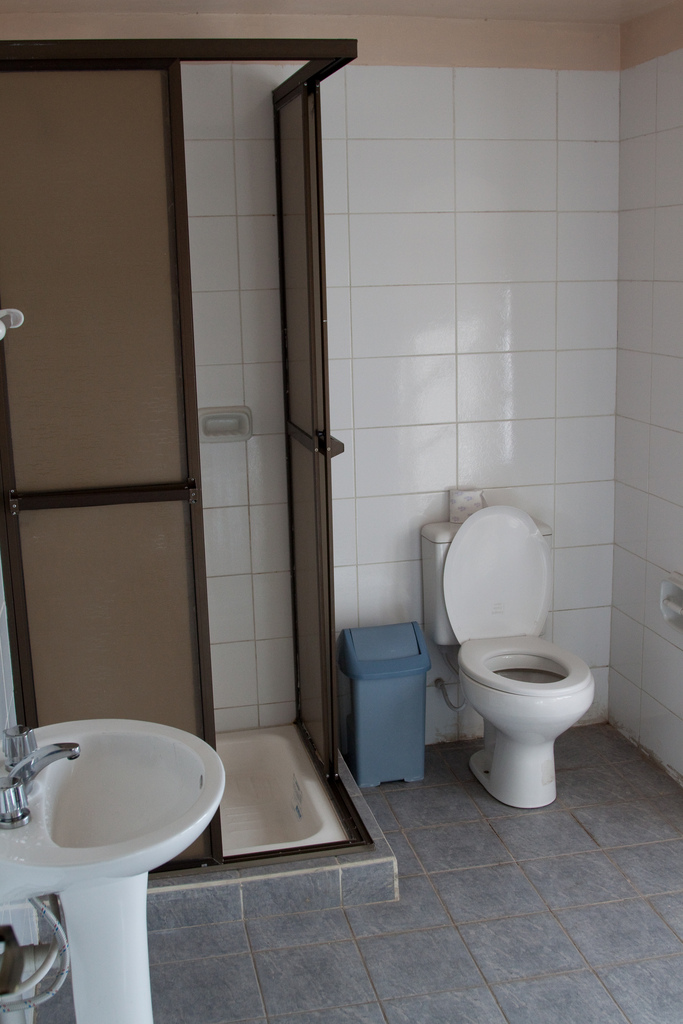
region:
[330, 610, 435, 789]
Waste bin next to toilet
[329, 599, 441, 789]
Waste bin is next to toilet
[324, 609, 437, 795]
Blue waste bin next to toilet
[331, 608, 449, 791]
Blue waste bin is next to toilet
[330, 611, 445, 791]
Trash bin next to toilet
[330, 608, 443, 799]
Trash bin is next to toilet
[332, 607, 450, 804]
Blue trash bin next to toilet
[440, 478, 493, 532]
Toilet paper on back of toilet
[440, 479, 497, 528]
Toilet paper roll is on back of toilet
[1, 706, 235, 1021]
white porcelain pedestal sink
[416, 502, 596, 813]
white porcelain toilet with open lid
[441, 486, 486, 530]
wrapped roll of toilet paper on tank of toilet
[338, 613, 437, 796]
blue plastic trash can next with swivel lid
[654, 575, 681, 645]
empty toilet paper holder on wall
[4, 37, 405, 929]
encosed shower stall with brown walls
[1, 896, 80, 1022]
water lines connecting wall to sink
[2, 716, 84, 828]
silver faucet on white pedestal sink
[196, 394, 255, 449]
small soap dish in wall of shower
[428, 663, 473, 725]
water line connecting toilet to wall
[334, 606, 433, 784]
Small blue trash can next to the shower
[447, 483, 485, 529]
Toilet paper roll on top of the toilet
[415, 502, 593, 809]
White toilet next to the blue trash can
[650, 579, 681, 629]
Toilet paper holder is empty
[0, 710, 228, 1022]
Sink next to the shower is white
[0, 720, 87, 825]
Silver faucet on the white sink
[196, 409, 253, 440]
White soap holder in the shower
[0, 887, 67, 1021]
Pipe under the faucet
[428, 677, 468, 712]
Pipe behind the toilet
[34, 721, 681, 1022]
Floor tile is gray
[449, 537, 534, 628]
lid of the toilet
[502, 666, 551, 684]
bowl of the toilet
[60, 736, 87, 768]
faucet of the sink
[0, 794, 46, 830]
knob on the sink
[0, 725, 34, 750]
knob on the sink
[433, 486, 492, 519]
box on the toilet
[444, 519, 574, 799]
White toilet in bathroom.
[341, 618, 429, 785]
Blue trash bin.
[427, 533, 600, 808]
a bathroom toilet is white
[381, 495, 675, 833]
a toilet is white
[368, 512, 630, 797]
a white toilet in the bathroom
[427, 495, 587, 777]
a toilet with lid up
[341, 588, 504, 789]
a blue garbage can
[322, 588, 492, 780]
a tall blue garbage can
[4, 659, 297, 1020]
a white bathroom sink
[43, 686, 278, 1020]
a sink in the bathroom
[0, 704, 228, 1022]
a white pedestal sink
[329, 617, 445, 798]
a blue trash can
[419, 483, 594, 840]
white ceramic toilet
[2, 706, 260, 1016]
ceramic white sink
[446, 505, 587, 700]
toilet lid is up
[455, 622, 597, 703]
toilet lid is round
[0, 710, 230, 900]
white sink is empty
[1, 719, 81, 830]
metal faucet is attached to sink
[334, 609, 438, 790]
garbage can next to toilet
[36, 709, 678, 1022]
bathroom floor covered in tile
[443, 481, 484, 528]
roll of toilet paper on top of tank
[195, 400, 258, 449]
soap dish attached to wall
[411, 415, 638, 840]
a bathroom toilet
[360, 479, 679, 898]
a whtie bathroom toilet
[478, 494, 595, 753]
a toilet in the bathroom